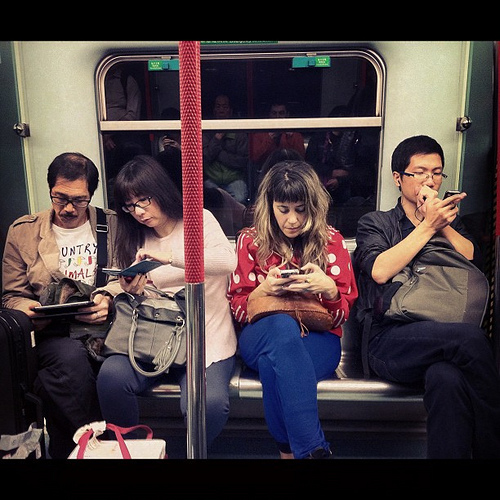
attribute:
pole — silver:
[176, 41, 209, 460]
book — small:
[101, 261, 158, 282]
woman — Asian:
[95, 152, 242, 460]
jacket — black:
[355, 196, 478, 378]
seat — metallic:
[135, 373, 442, 430]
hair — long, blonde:
[250, 158, 331, 275]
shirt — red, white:
[226, 221, 358, 339]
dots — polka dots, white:
[232, 268, 259, 285]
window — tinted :
[97, 56, 386, 174]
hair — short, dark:
[31, 145, 108, 197]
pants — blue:
[372, 310, 489, 468]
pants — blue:
[227, 310, 356, 474]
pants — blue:
[93, 341, 238, 461]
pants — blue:
[5, 317, 106, 438]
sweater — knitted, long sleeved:
[123, 200, 248, 376]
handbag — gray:
[249, 289, 334, 332]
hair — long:
[246, 154, 334, 282]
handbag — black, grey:
[104, 282, 189, 377]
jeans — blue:
[235, 312, 342, 452]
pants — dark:
[389, 307, 486, 480]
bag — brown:
[247, 290, 337, 333]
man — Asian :
[354, 134, 482, 461]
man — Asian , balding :
[4, 150, 130, 432]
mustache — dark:
[54, 210, 80, 220]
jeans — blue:
[374, 320, 480, 414]